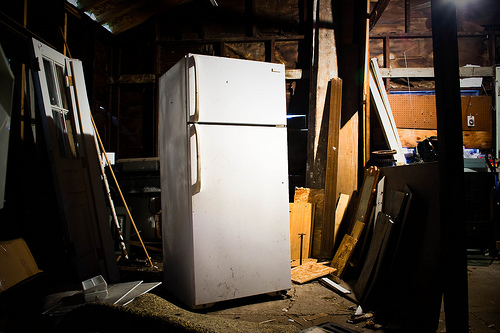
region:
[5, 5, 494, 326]
building materials and clutter in a basement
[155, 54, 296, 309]
white refrigerator with freezer on top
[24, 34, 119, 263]
old white door with windows leaning on a wall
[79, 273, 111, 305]
two white plastic ice makers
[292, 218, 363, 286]
leftover pieces of fiberboard on the floor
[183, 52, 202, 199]
handles of refrigerator and freezer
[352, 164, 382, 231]
discarded wood framed mirror leaning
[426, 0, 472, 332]
lolly column securing the floor above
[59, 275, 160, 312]
discarded white plastic boards or shelves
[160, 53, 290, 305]
an old white refrigerator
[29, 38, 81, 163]
windows on the white door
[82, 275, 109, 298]
two white ice cube trays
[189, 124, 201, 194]
refrigerator door handle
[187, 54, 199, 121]
freezer door handle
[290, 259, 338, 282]
piece of plywood on the ground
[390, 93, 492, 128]
a cork board on the wall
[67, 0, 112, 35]
light coming through the boards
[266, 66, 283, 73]
logo stamp on the door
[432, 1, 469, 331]
a wooden support beam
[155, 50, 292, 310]
a white refrigerator in a storage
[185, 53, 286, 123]
the freezer door on the refrigerator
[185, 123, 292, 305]
a refrigerator door below the freezer door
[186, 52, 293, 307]
two doors to the refrigerator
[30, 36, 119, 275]
an old white door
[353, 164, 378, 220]
a brown wooden framed mirror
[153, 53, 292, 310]
an old refrigerator in a garage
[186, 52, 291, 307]
a refrigerator with small freezer space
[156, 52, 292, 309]
a white two door refrigerator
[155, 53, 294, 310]
An old white refrigerator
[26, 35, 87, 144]
Top of a white window paneled door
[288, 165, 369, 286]
Several pieces of different sized plywood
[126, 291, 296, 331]
Piece of folded carpet padding on the ground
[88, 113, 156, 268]
Wooden handle of a mop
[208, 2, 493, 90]
Non-insulated wall of a garage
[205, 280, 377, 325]
Dirty and cracked concrete floor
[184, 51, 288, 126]
Freezer door of a refrigerator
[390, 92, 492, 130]
Corkboard hanging on a wall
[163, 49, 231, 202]
white handle on the fridge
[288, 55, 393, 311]
wood standing up in the garage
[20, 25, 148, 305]
door standing up in the garage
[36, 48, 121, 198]
door has a window on it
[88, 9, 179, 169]
building is made of wood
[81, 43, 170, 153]
the wood is brown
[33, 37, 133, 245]
the door is white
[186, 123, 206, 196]
Handle of a fridge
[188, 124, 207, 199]
Handle of a white fridge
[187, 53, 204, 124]
Handle of a fridge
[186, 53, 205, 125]
Handle of a white fridge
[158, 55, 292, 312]
Old fashioned white refrigerator and freezer combo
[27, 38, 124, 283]
Light colored old unused door with windows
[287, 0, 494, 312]
A lighted wood work area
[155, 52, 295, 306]
Plain white refrigerator with freezer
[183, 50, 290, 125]
Freezer door on old white refrigerator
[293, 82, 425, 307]
miscellaneous pieces of spare lumber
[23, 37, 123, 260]
white door with four window panes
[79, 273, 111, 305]
two white ice trays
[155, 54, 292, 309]
large upright refrigerator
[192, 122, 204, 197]
The handle of the fridge door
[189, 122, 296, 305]
The fridge door is closed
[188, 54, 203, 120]
The handle on the freezer door